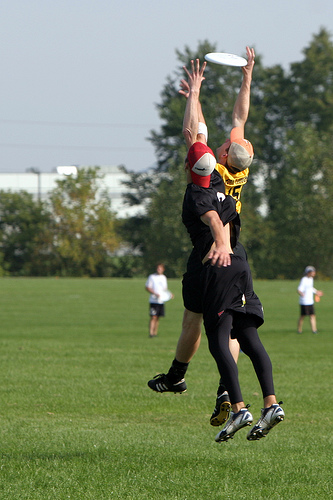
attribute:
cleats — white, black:
[144, 372, 230, 426]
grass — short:
[4, 282, 329, 499]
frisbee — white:
[205, 51, 251, 71]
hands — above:
[177, 46, 255, 100]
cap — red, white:
[185, 140, 217, 189]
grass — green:
[2, 276, 329, 448]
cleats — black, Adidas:
[138, 352, 246, 440]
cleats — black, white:
[245, 404, 289, 451]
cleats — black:
[211, 405, 254, 446]